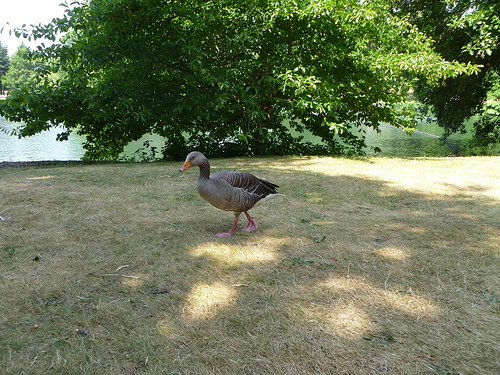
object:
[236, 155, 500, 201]
sunshine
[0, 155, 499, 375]
ground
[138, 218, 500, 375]
grass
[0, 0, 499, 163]
tree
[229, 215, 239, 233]
legs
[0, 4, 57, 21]
clouds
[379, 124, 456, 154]
gray stick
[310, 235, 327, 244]
leaves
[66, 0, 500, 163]
green leaves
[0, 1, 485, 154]
brown tree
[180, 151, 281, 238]
duck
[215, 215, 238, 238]
feet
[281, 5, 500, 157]
sunshine area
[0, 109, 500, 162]
river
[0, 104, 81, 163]
sunlight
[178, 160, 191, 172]
beak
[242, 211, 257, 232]
feet